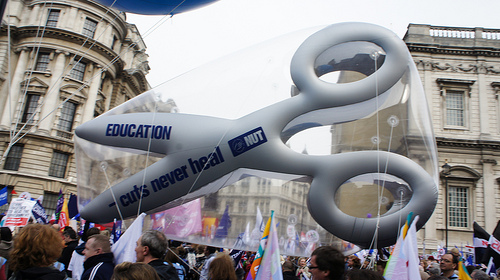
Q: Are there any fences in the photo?
A: No, there are no fences.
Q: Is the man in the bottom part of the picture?
A: Yes, the man is in the bottom of the image.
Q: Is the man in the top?
A: No, the man is in the bottom of the image.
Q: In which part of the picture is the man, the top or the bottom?
A: The man is in the bottom of the image.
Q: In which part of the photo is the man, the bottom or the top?
A: The man is in the bottom of the image.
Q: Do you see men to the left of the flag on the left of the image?
A: Yes, there is a man to the left of the flag.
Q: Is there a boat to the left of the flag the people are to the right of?
A: No, there is a man to the left of the flag.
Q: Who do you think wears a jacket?
A: The man wears a jacket.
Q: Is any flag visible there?
A: Yes, there is a flag.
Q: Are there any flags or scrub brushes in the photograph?
A: Yes, there is a flag.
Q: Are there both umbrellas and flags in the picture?
A: No, there is a flag but no umbrellas.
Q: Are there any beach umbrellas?
A: No, there are no beach umbrellas.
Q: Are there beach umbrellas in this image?
A: No, there are no beach umbrellas.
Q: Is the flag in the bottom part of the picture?
A: Yes, the flag is in the bottom of the image.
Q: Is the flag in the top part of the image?
A: No, the flag is in the bottom of the image.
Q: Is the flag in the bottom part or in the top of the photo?
A: The flag is in the bottom of the image.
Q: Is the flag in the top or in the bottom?
A: The flag is in the bottom of the image.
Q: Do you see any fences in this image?
A: No, there are no fences.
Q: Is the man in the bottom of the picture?
A: Yes, the man is in the bottom of the image.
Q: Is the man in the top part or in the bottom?
A: The man is in the bottom of the image.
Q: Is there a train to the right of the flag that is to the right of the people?
A: No, there is a man to the right of the flag.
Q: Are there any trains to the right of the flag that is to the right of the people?
A: No, there is a man to the right of the flag.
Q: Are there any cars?
A: No, there are no cars.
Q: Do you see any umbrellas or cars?
A: No, there are no cars or umbrellas.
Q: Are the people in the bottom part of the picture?
A: Yes, the people are in the bottom of the image.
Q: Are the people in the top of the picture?
A: No, the people are in the bottom of the image.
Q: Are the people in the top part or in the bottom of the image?
A: The people are in the bottom of the image.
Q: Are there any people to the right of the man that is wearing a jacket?
A: Yes, there are people to the right of the man.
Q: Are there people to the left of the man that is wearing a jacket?
A: No, the people are to the right of the man.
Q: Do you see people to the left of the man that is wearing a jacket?
A: No, the people are to the right of the man.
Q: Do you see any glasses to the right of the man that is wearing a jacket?
A: No, there are people to the right of the man.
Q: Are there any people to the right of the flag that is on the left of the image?
A: Yes, there are people to the right of the flag.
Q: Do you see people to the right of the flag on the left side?
A: Yes, there are people to the right of the flag.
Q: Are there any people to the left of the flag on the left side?
A: No, the people are to the right of the flag.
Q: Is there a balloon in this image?
A: Yes, there is a balloon.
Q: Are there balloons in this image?
A: Yes, there is a balloon.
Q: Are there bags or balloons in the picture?
A: Yes, there is a balloon.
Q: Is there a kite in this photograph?
A: No, there are no kites.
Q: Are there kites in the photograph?
A: No, there are no kites.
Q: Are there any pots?
A: No, there are no pots.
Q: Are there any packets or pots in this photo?
A: No, there are no pots or packets.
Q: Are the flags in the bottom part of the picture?
A: Yes, the flags are in the bottom of the image.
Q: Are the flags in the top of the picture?
A: No, the flags are in the bottom of the image.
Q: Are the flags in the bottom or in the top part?
A: The flags are in the bottom of the image.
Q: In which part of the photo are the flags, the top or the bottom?
A: The flags are in the bottom of the image.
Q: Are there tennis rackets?
A: No, there are no tennis rackets.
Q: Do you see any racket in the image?
A: No, there are no rackets.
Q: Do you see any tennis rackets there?
A: No, there are no tennis rackets.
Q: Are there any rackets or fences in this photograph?
A: No, there are no rackets or fences.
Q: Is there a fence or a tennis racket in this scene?
A: No, there are no rackets or fences.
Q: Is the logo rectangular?
A: Yes, the logo is rectangular.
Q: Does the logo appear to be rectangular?
A: Yes, the logo is rectangular.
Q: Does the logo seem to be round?
A: No, the logo is rectangular.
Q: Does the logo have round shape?
A: No, the logo is rectangular.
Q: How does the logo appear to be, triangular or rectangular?
A: The logo is rectangular.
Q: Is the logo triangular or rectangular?
A: The logo is rectangular.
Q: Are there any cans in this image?
A: No, there are no cans.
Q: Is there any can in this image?
A: No, there are no cans.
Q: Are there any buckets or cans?
A: No, there are no cans or buckets.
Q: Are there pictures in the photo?
A: No, there are no pictures.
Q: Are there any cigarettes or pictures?
A: No, there are no pictures or cigarettes.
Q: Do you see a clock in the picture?
A: No, there are no clocks.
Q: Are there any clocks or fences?
A: No, there are no clocks or fences.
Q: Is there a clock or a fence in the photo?
A: No, there are no clocks or fences.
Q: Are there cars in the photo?
A: No, there are no cars.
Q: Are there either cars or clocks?
A: No, there are no cars or clocks.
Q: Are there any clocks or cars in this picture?
A: No, there are no cars or clocks.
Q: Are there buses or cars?
A: No, there are no cars or buses.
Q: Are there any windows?
A: Yes, there is a window.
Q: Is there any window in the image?
A: Yes, there is a window.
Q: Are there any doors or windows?
A: Yes, there is a window.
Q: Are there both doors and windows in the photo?
A: No, there is a window but no doors.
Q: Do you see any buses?
A: No, there are no buses.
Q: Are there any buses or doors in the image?
A: No, there are no buses or doors.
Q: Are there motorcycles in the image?
A: No, there are no motorcycles.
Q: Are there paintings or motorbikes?
A: No, there are no motorbikes or paintings.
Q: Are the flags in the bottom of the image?
A: Yes, the flags are in the bottom of the image.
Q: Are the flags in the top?
A: No, the flags are in the bottom of the image.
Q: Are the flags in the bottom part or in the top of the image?
A: The flags are in the bottom of the image.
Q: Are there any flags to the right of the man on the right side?
A: Yes, there are flags to the right of the man.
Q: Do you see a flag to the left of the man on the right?
A: No, the flags are to the right of the man.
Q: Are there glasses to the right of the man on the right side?
A: No, there are flags to the right of the man.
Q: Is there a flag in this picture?
A: Yes, there is a flag.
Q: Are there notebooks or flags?
A: Yes, there is a flag.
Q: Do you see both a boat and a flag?
A: No, there is a flag but no boats.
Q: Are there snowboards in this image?
A: No, there are no snowboards.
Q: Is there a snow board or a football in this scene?
A: No, there are no snowboards or footballs.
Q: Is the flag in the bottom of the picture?
A: Yes, the flag is in the bottom of the image.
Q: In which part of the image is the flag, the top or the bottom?
A: The flag is in the bottom of the image.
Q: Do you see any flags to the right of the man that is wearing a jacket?
A: Yes, there is a flag to the right of the man.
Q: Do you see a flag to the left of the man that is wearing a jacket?
A: No, the flag is to the right of the man.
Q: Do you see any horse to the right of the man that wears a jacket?
A: No, there is a flag to the right of the man.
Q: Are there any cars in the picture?
A: No, there are no cars.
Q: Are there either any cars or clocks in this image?
A: No, there are no cars or clocks.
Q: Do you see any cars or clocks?
A: No, there are no cars or clocks.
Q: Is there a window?
A: Yes, there is a window.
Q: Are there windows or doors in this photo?
A: Yes, there is a window.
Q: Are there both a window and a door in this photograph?
A: No, there is a window but no doors.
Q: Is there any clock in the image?
A: No, there are no clocks.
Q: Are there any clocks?
A: No, there are no clocks.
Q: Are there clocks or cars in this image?
A: No, there are no clocks or cars.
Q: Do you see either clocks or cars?
A: No, there are no clocks or cars.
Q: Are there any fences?
A: No, there are no fences.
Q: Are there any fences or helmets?
A: No, there are no fences or helmets.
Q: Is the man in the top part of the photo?
A: No, the man is in the bottom of the image.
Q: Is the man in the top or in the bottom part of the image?
A: The man is in the bottom of the image.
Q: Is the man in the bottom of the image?
A: Yes, the man is in the bottom of the image.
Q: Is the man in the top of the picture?
A: No, the man is in the bottom of the image.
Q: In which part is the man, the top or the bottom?
A: The man is in the bottom of the image.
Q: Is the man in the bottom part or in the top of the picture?
A: The man is in the bottom of the image.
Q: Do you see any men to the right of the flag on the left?
A: Yes, there is a man to the right of the flag.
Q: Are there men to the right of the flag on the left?
A: Yes, there is a man to the right of the flag.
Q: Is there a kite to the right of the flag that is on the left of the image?
A: No, there is a man to the right of the flag.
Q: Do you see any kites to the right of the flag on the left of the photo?
A: No, there is a man to the right of the flag.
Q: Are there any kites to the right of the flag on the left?
A: No, there is a man to the right of the flag.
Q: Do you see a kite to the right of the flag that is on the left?
A: No, there is a man to the right of the flag.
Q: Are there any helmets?
A: No, there are no helmets.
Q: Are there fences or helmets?
A: No, there are no helmets or fences.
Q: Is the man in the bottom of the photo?
A: Yes, the man is in the bottom of the image.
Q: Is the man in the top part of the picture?
A: No, the man is in the bottom of the image.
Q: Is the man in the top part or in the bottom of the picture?
A: The man is in the bottom of the image.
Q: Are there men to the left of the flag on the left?
A: Yes, there is a man to the left of the flag.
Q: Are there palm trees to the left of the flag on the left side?
A: No, there is a man to the left of the flag.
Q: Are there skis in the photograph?
A: No, there are no skis.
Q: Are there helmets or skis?
A: No, there are no skis or helmets.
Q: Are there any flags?
A: Yes, there is a flag.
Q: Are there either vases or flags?
A: Yes, there is a flag.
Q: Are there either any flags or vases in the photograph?
A: Yes, there is a flag.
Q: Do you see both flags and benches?
A: No, there is a flag but no benches.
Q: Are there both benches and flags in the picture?
A: No, there is a flag but no benches.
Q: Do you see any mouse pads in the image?
A: No, there are no mouse pads.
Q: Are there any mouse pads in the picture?
A: No, there are no mouse pads.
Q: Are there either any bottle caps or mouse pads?
A: No, there are no mouse pads or bottle caps.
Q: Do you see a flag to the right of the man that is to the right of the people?
A: Yes, there is a flag to the right of the man.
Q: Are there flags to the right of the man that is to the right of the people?
A: Yes, there is a flag to the right of the man.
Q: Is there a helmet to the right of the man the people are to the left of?
A: No, there is a flag to the right of the man.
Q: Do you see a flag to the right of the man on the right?
A: Yes, there is a flag to the right of the man.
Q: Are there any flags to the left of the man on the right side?
A: No, the flag is to the right of the man.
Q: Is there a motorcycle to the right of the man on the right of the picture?
A: No, there is a flag to the right of the man.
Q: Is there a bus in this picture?
A: No, there are no buses.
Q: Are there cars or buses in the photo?
A: No, there are no buses or cars.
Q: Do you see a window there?
A: Yes, there is a window.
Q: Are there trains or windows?
A: Yes, there is a window.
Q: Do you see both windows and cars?
A: No, there is a window but no cars.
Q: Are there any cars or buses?
A: No, there are no buses or cars.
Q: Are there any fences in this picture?
A: No, there are no fences.